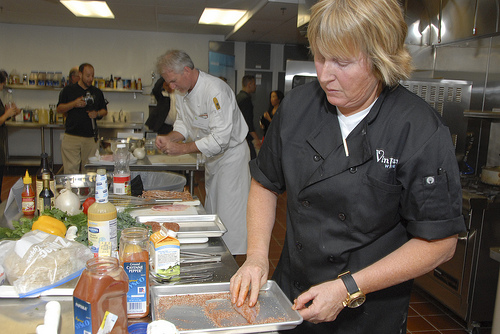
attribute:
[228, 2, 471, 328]
person — wearing watch, looking, wearing, preparing food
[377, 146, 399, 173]
logo — white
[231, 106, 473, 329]
shirt — black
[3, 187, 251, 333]
table — silver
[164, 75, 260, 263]
uniform — white, wearing coat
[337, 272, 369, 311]
watch — gold, wristwatch, black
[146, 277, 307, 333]
tray — silver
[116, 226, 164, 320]
container — open, plastic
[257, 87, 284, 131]
woman — talking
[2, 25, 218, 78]
paint — white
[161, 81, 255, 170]
coat — white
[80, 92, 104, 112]
man — holding camera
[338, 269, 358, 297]
strap — black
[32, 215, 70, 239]
pepper — yellow, orange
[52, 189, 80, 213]
onion — white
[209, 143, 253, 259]
apron — white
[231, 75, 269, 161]
man — talking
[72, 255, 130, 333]
carton — blue, crushed